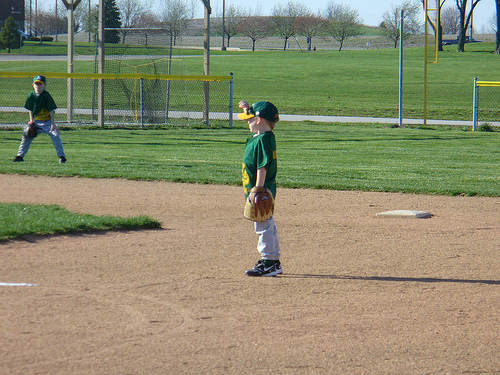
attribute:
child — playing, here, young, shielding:
[238, 100, 280, 277]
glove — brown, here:
[243, 187, 275, 223]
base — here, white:
[374, 207, 433, 219]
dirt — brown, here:
[0, 173, 500, 375]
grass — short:
[1, 41, 499, 199]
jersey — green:
[240, 132, 278, 203]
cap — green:
[239, 101, 280, 123]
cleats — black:
[246, 259, 282, 277]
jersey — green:
[24, 90, 58, 123]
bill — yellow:
[233, 113, 255, 120]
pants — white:
[253, 214, 281, 261]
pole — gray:
[97, 0, 105, 129]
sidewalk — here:
[2, 106, 500, 128]